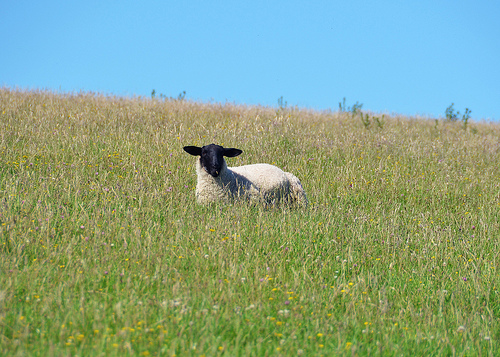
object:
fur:
[195, 163, 309, 207]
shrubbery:
[338, 96, 474, 128]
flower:
[0, 194, 499, 357]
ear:
[182, 145, 201, 156]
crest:
[0, 74, 499, 135]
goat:
[181, 143, 309, 210]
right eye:
[202, 149, 208, 154]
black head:
[181, 144, 242, 178]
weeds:
[0, 85, 498, 143]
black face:
[199, 143, 224, 177]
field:
[1, 84, 500, 357]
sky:
[4, 0, 499, 121]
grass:
[0, 84, 499, 357]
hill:
[0, 89, 499, 357]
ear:
[223, 147, 243, 157]